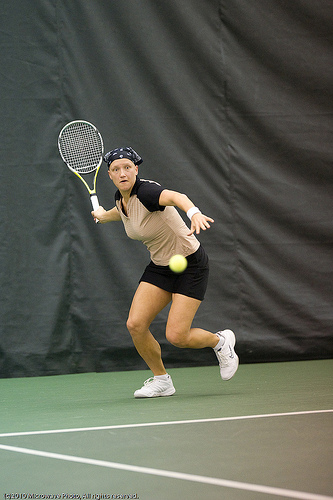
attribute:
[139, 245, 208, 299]
shorts — black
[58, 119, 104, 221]
racket — yellow and grey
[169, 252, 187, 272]
ball — yellow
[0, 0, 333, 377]
tarp — grey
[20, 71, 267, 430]
woman — playing